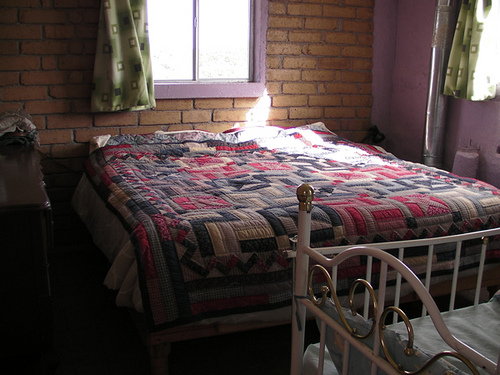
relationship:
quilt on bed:
[119, 139, 499, 327] [67, 99, 499, 331]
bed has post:
[288, 180, 498, 374] [289, 180, 317, 371]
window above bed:
[150, 0, 263, 98] [81, 128, 499, 344]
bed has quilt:
[81, 128, 499, 344] [88, 129, 499, 333]